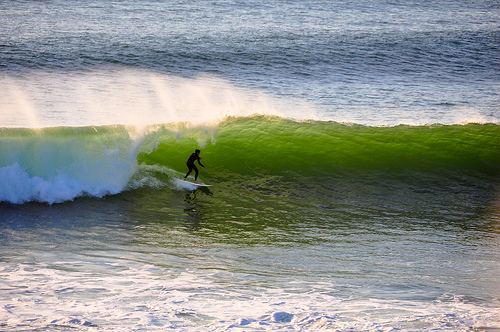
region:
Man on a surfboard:
[170, 119, 232, 221]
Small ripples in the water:
[16, 270, 68, 319]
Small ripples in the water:
[91, 294, 131, 329]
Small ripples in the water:
[140, 266, 179, 304]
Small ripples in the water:
[168, 288, 208, 329]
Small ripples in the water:
[182, 249, 239, 289]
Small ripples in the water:
[241, 281, 298, 329]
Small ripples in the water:
[289, 247, 325, 290]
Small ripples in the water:
[337, 281, 395, 329]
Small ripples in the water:
[385, 232, 455, 297]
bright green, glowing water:
[0, 113, 498, 247]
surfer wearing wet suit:
[181, 149, 204, 184]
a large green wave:
[0, 109, 499, 208]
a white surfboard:
[169, 173, 213, 188]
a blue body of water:
[0, 0, 499, 123]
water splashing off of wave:
[0, 73, 310, 125]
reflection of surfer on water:
[176, 179, 214, 234]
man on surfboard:
[184, 147, 207, 181]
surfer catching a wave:
[181, 146, 206, 184]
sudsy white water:
[1, 257, 499, 330]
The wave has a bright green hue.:
[2, 3, 499, 330]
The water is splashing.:
[0, 0, 499, 330]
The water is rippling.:
[0, 2, 499, 330]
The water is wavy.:
[1, 1, 498, 329]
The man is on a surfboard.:
[160, 128, 242, 229]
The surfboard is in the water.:
[116, 129, 321, 252]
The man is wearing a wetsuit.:
[137, 115, 277, 235]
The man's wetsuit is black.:
[146, 100, 283, 262]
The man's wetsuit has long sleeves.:
[141, 124, 276, 215]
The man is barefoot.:
[151, 104, 274, 235]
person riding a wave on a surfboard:
[182, 144, 206, 182]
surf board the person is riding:
[176, 171, 208, 191]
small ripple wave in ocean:
[480, 25, 490, 32]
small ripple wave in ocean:
[271, 309, 291, 320]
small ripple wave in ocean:
[358, 263, 371, 273]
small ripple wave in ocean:
[63, 283, 105, 302]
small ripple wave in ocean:
[126, 28, 142, 30]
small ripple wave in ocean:
[298, 52, 319, 62]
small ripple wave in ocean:
[375, 14, 392, 23]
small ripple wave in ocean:
[404, 312, 436, 322]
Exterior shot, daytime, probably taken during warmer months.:
[5, 6, 497, 331]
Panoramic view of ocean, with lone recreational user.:
[0, 0, 499, 330]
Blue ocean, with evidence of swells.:
[70, 3, 471, 80]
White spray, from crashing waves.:
[15, 67, 277, 112]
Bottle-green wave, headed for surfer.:
[227, 109, 490, 214]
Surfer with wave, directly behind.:
[175, 143, 210, 198]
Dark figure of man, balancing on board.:
[187, 146, 209, 184]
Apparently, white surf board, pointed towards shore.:
[184, 178, 207, 200]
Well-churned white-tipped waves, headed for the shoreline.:
[91, 238, 488, 330]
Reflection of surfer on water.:
[174, 194, 218, 233]